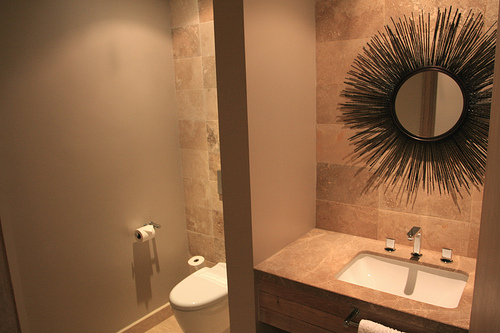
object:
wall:
[305, 0, 497, 260]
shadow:
[133, 242, 154, 308]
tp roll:
[133, 225, 156, 243]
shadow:
[402, 266, 420, 294]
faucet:
[407, 226, 424, 257]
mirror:
[395, 69, 465, 140]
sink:
[335, 250, 468, 309]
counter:
[252, 227, 478, 330]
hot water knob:
[384, 238, 395, 252]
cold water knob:
[442, 247, 453, 263]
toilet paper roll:
[188, 256, 206, 272]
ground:
[131, 311, 186, 332]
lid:
[169, 262, 230, 309]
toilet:
[0, 0, 500, 332]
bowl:
[168, 300, 231, 333]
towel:
[359, 319, 409, 332]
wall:
[0, 0, 192, 332]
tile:
[167, 0, 230, 259]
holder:
[149, 222, 161, 229]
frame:
[336, 6, 496, 215]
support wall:
[213, 1, 314, 331]